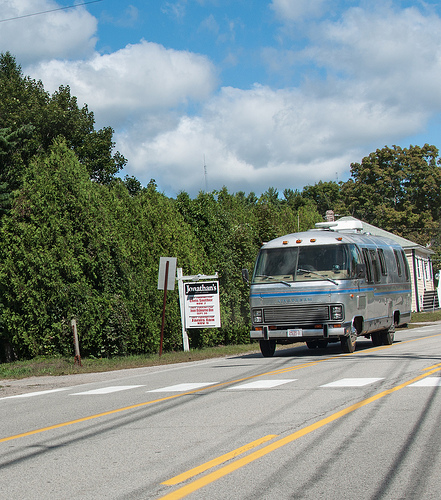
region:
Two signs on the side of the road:
[135, 249, 232, 344]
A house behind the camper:
[240, 209, 435, 362]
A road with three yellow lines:
[0, 325, 433, 493]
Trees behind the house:
[332, 143, 437, 356]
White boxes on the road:
[50, 367, 425, 389]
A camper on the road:
[216, 196, 413, 413]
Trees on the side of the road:
[0, 165, 340, 373]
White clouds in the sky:
[17, 15, 433, 170]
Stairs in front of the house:
[403, 242, 435, 306]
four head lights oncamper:
[242, 286, 349, 356]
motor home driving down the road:
[242, 219, 412, 356]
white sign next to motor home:
[183, 279, 221, 328]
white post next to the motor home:
[172, 266, 219, 350]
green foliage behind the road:
[0, 48, 440, 353]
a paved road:
[0, 317, 439, 498]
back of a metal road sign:
[155, 254, 177, 291]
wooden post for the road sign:
[159, 259, 170, 357]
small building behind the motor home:
[324, 208, 438, 311]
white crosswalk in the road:
[6, 374, 440, 401]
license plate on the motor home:
[288, 327, 305, 338]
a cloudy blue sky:
[0, 0, 439, 197]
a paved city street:
[2, 319, 437, 497]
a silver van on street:
[246, 227, 415, 354]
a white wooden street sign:
[173, 266, 222, 350]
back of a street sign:
[154, 254, 176, 292]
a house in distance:
[333, 211, 436, 317]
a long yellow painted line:
[155, 362, 439, 498]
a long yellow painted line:
[2, 330, 440, 442]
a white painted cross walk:
[10, 375, 440, 397]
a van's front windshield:
[256, 245, 351, 282]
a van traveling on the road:
[242, 216, 415, 355]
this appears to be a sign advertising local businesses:
[174, 262, 228, 353]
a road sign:
[148, 249, 178, 361]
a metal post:
[65, 307, 92, 368]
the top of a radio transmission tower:
[193, 148, 221, 204]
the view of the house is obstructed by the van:
[299, 204, 440, 339]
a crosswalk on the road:
[2, 372, 440, 405]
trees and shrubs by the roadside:
[0, 45, 141, 368]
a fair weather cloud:
[196, 79, 439, 170]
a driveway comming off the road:
[2, 354, 155, 396]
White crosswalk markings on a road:
[1, 375, 440, 397]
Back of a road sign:
[156, 254, 178, 358]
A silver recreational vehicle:
[242, 226, 416, 355]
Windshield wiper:
[296, 266, 337, 284]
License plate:
[284, 325, 302, 338]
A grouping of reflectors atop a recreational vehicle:
[281, 236, 316, 244]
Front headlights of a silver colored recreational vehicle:
[249, 300, 348, 323]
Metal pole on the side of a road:
[65, 313, 80, 366]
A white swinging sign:
[175, 266, 222, 351]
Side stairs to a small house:
[421, 287, 439, 312]